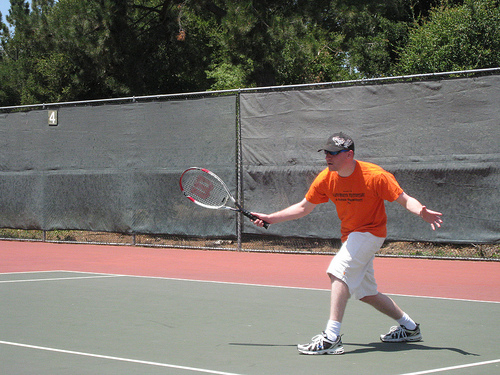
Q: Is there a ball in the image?
A: No, there are no balls.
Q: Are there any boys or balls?
A: No, there are no balls or boys.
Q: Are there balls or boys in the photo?
A: No, there are no balls or boys.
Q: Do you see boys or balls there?
A: No, there are no balls or boys.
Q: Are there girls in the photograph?
A: No, there are no girls.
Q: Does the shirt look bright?
A: Yes, the shirt is bright.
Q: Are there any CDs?
A: No, there are no cds.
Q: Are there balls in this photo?
A: No, there are no balls.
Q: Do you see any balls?
A: No, there are no balls.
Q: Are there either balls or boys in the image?
A: No, there are no balls or boys.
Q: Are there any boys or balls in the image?
A: No, there are no balls or boys.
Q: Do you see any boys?
A: No, there are no boys.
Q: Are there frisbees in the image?
A: No, there are no frisbees.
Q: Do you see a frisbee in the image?
A: No, there are no frisbees.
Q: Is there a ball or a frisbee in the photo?
A: No, there are no frisbees or balls.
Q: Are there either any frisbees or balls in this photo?
A: No, there are no frisbees or balls.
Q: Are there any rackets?
A: Yes, there is a racket.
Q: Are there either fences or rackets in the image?
A: Yes, there is a racket.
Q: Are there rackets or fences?
A: Yes, there is a racket.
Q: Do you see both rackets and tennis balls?
A: No, there is a racket but no tennis balls.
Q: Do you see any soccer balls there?
A: No, there are no soccer balls.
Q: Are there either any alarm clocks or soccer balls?
A: No, there are no soccer balls or alarm clocks.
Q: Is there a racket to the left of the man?
A: Yes, there is a racket to the left of the man.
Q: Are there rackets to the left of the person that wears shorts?
A: Yes, there is a racket to the left of the man.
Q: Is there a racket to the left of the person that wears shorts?
A: Yes, there is a racket to the left of the man.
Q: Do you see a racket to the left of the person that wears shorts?
A: Yes, there is a racket to the left of the man.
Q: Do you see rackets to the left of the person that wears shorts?
A: Yes, there is a racket to the left of the man.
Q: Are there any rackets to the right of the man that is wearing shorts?
A: No, the racket is to the left of the man.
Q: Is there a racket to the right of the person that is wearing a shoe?
A: No, the racket is to the left of the man.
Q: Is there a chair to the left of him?
A: No, there is a racket to the left of the man.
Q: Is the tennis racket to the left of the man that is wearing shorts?
A: Yes, the tennis racket is to the left of the man.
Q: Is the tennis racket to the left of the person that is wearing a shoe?
A: Yes, the tennis racket is to the left of the man.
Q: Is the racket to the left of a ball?
A: No, the racket is to the left of the man.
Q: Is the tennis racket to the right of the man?
A: No, the tennis racket is to the left of the man.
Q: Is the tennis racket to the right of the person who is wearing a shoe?
A: No, the tennis racket is to the left of the man.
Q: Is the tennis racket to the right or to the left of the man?
A: The tennis racket is to the left of the man.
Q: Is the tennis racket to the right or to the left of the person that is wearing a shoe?
A: The tennis racket is to the left of the man.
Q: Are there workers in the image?
A: No, there are no workers.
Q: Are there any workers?
A: No, there are no workers.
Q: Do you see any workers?
A: No, there are no workers.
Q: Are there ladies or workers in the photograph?
A: No, there are no workers or ladies.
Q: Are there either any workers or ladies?
A: No, there are no workers or ladies.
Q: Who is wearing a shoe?
A: The man is wearing a shoe.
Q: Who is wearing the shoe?
A: The man is wearing a shoe.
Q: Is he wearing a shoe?
A: Yes, the man is wearing a shoe.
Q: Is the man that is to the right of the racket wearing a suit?
A: No, the man is wearing a shoe.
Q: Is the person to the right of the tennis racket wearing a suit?
A: No, the man is wearing a shoe.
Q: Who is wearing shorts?
A: The man is wearing shorts.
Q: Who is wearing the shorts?
A: The man is wearing shorts.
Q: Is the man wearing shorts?
A: Yes, the man is wearing shorts.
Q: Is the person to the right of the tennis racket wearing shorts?
A: Yes, the man is wearing shorts.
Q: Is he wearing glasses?
A: No, the man is wearing shorts.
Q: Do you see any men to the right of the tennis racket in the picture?
A: Yes, there is a man to the right of the tennis racket.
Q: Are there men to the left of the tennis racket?
A: No, the man is to the right of the tennis racket.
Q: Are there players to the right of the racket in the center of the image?
A: No, there is a man to the right of the racket.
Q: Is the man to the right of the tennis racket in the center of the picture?
A: Yes, the man is to the right of the racket.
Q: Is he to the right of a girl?
A: No, the man is to the right of the racket.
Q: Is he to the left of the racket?
A: No, the man is to the right of the racket.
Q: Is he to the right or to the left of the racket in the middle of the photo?
A: The man is to the right of the racket.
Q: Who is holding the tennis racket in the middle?
A: The man is holding the tennis racket.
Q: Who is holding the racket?
A: The man is holding the tennis racket.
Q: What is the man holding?
A: The man is holding the racket.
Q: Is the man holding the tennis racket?
A: Yes, the man is holding the tennis racket.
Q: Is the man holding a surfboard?
A: No, the man is holding the tennis racket.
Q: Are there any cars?
A: No, there are no cars.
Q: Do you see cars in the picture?
A: No, there are no cars.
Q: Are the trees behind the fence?
A: Yes, the trees are behind the fence.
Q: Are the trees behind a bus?
A: No, the trees are behind the fence.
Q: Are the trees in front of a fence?
A: No, the trees are behind a fence.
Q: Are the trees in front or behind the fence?
A: The trees are behind the fence.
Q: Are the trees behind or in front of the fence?
A: The trees are behind the fence.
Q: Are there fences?
A: Yes, there is a fence.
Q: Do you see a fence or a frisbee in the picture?
A: Yes, there is a fence.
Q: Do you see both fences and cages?
A: No, there is a fence but no cages.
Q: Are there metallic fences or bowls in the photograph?
A: Yes, there is a metal fence.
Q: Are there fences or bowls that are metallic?
A: Yes, the fence is metallic.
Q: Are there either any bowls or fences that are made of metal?
A: Yes, the fence is made of metal.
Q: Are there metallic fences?
A: Yes, there is a metal fence.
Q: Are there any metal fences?
A: Yes, there is a metal fence.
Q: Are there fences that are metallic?
A: Yes, there is a fence that is metallic.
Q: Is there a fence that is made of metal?
A: Yes, there is a fence that is made of metal.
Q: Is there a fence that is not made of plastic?
A: Yes, there is a fence that is made of metal.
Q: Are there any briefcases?
A: No, there are no briefcases.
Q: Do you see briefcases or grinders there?
A: No, there are no briefcases or grinders.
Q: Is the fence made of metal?
A: Yes, the fence is made of metal.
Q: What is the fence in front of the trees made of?
A: The fence is made of metal.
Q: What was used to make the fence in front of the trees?
A: The fence is made of metal.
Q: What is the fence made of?
A: The fence is made of metal.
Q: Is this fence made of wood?
A: No, the fence is made of metal.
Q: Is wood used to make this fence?
A: No, the fence is made of metal.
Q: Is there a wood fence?
A: No, there is a fence but it is made of metal.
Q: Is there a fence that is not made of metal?
A: No, there is a fence but it is made of metal.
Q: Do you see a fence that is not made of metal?
A: No, there is a fence but it is made of metal.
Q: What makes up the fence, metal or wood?
A: The fence is made of metal.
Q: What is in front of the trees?
A: The fence is in front of the trees.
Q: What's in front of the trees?
A: The fence is in front of the trees.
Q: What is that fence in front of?
A: The fence is in front of the trees.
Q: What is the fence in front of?
A: The fence is in front of the trees.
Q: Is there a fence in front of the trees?
A: Yes, there is a fence in front of the trees.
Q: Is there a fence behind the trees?
A: No, the fence is in front of the trees.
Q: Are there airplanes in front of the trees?
A: No, there is a fence in front of the trees.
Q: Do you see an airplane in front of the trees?
A: No, there is a fence in front of the trees.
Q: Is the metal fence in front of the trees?
A: Yes, the fence is in front of the trees.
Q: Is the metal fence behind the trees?
A: No, the fence is in front of the trees.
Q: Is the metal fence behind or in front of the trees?
A: The fence is in front of the trees.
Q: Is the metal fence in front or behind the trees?
A: The fence is in front of the trees.